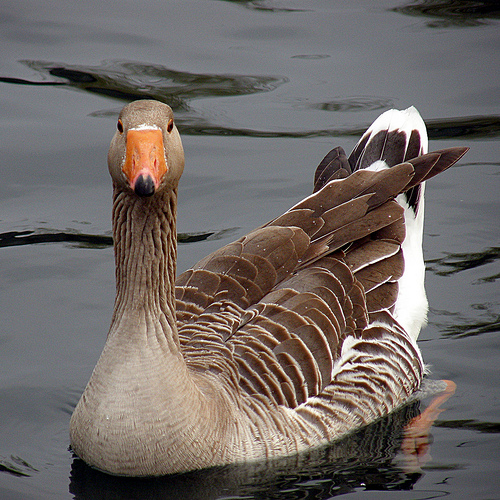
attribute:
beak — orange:
[118, 123, 171, 200]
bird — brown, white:
[66, 96, 470, 478]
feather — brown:
[306, 189, 378, 245]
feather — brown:
[343, 233, 402, 274]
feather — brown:
[354, 249, 405, 296]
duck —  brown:
[66, 96, 470, 478]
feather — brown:
[364, 279, 400, 312]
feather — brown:
[318, 255, 356, 294]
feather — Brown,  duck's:
[274, 206, 323, 229]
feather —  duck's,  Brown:
[274, 208, 326, 231]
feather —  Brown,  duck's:
[274, 206, 323, 236]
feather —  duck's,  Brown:
[267, 208, 332, 229]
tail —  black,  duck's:
[314, 146, 348, 193]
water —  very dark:
[2, 4, 496, 276]